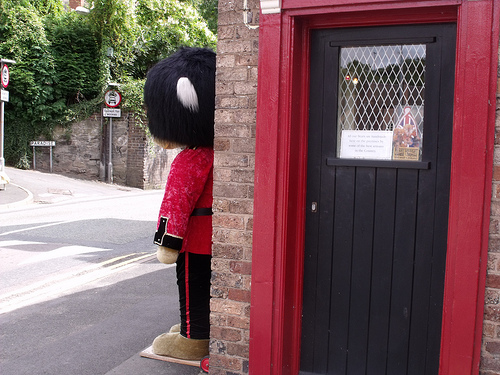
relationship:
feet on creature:
[154, 321, 208, 360] [141, 45, 215, 360]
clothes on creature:
[153, 148, 211, 338] [141, 45, 215, 360]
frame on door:
[247, 0, 497, 372] [301, 25, 454, 373]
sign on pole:
[30, 139, 54, 147] [32, 145, 36, 166]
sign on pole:
[30, 139, 54, 147] [49, 146, 53, 172]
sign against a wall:
[30, 139, 54, 147] [28, 110, 145, 186]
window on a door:
[336, 44, 426, 159] [285, 21, 453, 370]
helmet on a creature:
[142, 47, 215, 146] [141, 45, 215, 360]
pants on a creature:
[175, 251, 210, 339] [141, 45, 215, 360]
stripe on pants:
[182, 252, 188, 337] [175, 251, 210, 339]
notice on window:
[340, 127, 395, 158] [336, 44, 426, 159]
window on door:
[336, 44, 426, 159] [285, 21, 453, 370]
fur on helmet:
[176, 75, 199, 110] [142, 47, 215, 146]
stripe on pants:
[184, 252, 189, 337] [175, 251, 210, 339]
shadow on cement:
[5, 212, 190, 273] [1, 185, 195, 373]